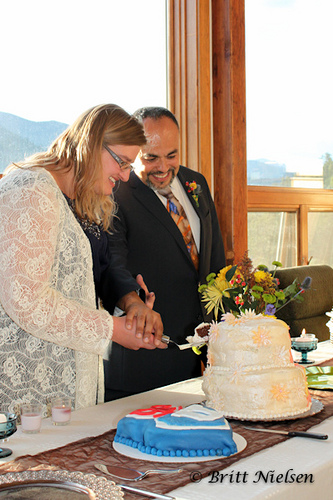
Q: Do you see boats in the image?
A: No, there are no boats.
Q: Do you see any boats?
A: No, there are no boats.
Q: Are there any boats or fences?
A: No, there are no boats or fences.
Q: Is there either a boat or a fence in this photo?
A: No, there are no boats or fences.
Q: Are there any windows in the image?
A: Yes, there are windows.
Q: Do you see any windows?
A: Yes, there are windows.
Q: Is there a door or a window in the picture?
A: Yes, there are windows.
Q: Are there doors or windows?
A: Yes, there are windows.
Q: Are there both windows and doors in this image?
A: No, there are windows but no doors.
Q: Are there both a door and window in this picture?
A: No, there are windows but no doors.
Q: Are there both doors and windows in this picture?
A: No, there are windows but no doors.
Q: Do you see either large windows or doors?
A: Yes, there are large windows.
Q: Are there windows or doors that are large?
A: Yes, the windows are large.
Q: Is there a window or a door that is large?
A: Yes, the windows are large.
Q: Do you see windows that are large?
A: Yes, there are large windows.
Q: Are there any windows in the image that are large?
A: Yes, there are windows that are large.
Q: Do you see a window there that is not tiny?
A: Yes, there are large windows.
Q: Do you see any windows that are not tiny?
A: Yes, there are large windows.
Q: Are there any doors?
A: No, there are no doors.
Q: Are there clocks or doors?
A: No, there are no doors or clocks.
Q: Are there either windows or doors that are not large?
A: No, there are windows but they are large.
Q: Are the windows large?
A: Yes, the windows are large.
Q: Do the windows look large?
A: Yes, the windows are large.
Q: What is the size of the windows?
A: The windows are large.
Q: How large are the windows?
A: The windows are large.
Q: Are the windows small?
A: No, the windows are large.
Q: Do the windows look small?
A: No, the windows are large.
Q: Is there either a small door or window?
A: No, there are windows but they are large.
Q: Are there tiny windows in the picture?
A: No, there are windows but they are large.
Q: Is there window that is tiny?
A: No, there are windows but they are large.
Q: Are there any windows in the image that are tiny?
A: No, there are windows but they are large.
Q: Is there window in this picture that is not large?
A: No, there are windows but they are large.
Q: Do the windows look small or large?
A: The windows are large.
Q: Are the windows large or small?
A: The windows are large.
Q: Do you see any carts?
A: No, there are no carts.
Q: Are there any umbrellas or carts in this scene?
A: No, there are no carts or umbrellas.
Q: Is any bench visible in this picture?
A: No, there are no benches.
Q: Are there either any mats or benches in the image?
A: No, there are no benches or mats.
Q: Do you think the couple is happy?
A: Yes, the couple is happy.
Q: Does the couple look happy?
A: Yes, the couple is happy.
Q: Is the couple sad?
A: No, the couple is happy.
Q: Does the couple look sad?
A: No, the couple is happy.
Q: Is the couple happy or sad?
A: The couple is happy.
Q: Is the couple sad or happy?
A: The couple is happy.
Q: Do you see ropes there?
A: No, there are no ropes.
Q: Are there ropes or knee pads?
A: No, there are no ropes or knee pads.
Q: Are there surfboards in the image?
A: No, there are no surfboards.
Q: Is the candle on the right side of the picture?
A: Yes, the candle is on the right of the image.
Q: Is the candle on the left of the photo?
A: No, the candle is on the right of the image.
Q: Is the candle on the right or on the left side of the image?
A: The candle is on the right of the image.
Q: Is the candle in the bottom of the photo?
A: Yes, the candle is in the bottom of the image.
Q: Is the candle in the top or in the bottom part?
A: The candle is in the bottom of the image.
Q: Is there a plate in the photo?
A: Yes, there is a plate.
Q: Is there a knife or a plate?
A: Yes, there is a plate.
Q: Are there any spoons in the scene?
A: No, there are no spoons.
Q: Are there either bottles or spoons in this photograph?
A: No, there are no spoons or bottles.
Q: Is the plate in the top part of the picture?
A: No, the plate is in the bottom of the image.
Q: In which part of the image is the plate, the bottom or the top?
A: The plate is in the bottom of the image.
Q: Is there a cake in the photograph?
A: Yes, there is a cake.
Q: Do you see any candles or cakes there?
A: Yes, there is a cake.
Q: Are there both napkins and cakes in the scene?
A: No, there is a cake but no napkins.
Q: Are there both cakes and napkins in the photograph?
A: No, there is a cake but no napkins.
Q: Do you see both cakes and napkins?
A: No, there is a cake but no napkins.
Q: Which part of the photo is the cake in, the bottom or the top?
A: The cake is in the bottom of the image.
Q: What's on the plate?
A: The cake is on the plate.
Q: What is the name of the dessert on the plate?
A: The dessert is a cake.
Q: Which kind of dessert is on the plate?
A: The dessert is a cake.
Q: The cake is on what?
A: The cake is on the plate.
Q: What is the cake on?
A: The cake is on the plate.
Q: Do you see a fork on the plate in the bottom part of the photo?
A: No, there is a cake on the plate.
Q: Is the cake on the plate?
A: Yes, the cake is on the plate.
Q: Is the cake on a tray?
A: No, the cake is on the plate.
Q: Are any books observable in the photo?
A: No, there are no books.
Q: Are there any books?
A: No, there are no books.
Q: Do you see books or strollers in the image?
A: No, there are no books or strollers.